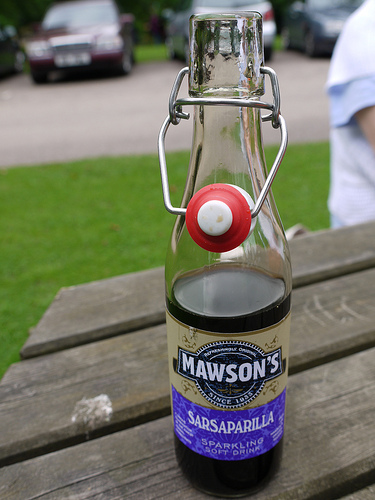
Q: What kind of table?
A: Wooden.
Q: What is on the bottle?
A: Label.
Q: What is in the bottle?
A: Liquid.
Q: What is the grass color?
A: Green.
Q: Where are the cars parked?
A: Background.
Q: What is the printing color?
A: White.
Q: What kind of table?
A: Picnic.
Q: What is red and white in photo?
A: Bottle sealer.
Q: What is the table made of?
A: Wood.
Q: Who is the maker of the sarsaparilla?
A: Mawson's.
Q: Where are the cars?
A: Parking spots.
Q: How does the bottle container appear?
A: Clear.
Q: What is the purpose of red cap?
A: Seals freshness.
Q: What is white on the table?
A: Bird poop.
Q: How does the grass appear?
A: Green and lush.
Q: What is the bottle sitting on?
A: A brown, wooden table.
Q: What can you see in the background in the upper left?
A: An out of focus car.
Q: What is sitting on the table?
A: A bottle of Mawson's Sasaparilla.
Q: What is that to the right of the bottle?
A: An out of focus person wearing a t-shirt.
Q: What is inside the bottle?
A: Soft drink.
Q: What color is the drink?
A: Dark brown.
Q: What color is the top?
A: Red.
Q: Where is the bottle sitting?
A: On the table.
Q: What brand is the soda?
A: Mawsons.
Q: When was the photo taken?
A: Daytime.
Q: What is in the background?
A: Cars.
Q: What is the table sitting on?
A: Grass.